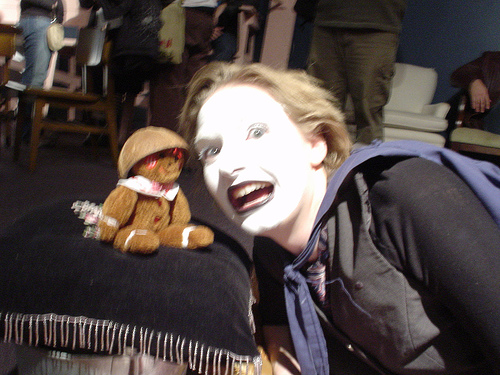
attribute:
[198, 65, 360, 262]
woman — watching, looking, white, visable, close, here, blonde, younger, staring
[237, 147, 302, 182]
makeup — white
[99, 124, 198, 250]
bear — small, brown, teddy 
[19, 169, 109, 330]
pillow — visable, black, blue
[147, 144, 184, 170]
eyes — red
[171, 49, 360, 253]
hair — blonde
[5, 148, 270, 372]
pillow — black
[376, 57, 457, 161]
chair — white 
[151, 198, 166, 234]
buttons — red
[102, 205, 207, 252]
lines — white 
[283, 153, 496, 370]
shirt — black 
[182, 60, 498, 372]
mime — scary 